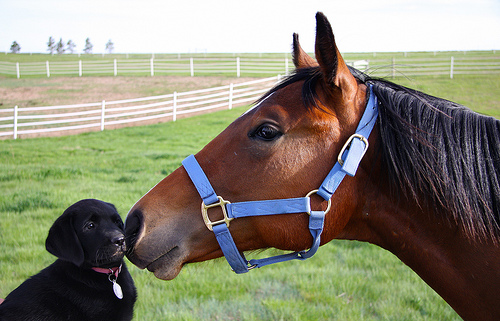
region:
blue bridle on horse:
[177, 155, 320, 307]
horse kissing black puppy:
[109, 206, 171, 272]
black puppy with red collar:
[48, 204, 133, 301]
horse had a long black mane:
[376, 90, 446, 172]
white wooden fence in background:
[71, 108, 129, 149]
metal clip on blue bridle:
[194, 190, 226, 253]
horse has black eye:
[245, 113, 270, 160]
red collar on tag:
[106, 278, 140, 315]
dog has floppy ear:
[46, 220, 73, 260]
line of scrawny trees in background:
[48, 34, 120, 77]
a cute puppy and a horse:
[45, 23, 445, 313]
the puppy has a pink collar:
[88, 259, 148, 277]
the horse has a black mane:
[351, 86, 498, 213]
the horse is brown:
[115, 8, 499, 290]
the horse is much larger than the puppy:
[6, 6, 485, 318]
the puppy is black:
[0, 190, 145, 318]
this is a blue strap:
[179, 75, 384, 272]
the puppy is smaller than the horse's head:
[0, 16, 392, 317]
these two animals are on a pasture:
[6, 10, 492, 317]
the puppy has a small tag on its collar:
[106, 270, 137, 310]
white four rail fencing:
[6, 86, 202, 141]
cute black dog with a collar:
[1, 183, 126, 318]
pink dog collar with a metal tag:
[88, 263, 131, 304]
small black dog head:
[43, 191, 125, 267]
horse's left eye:
[239, 116, 291, 159]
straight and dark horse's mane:
[376, 81, 498, 272]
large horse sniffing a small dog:
[0, 8, 497, 318]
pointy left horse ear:
[310, 10, 359, 85]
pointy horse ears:
[276, 8, 373, 93]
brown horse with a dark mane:
[124, 8, 498, 319]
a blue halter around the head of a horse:
[179, 78, 388, 277]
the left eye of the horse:
[247, 122, 287, 143]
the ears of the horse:
[290, 9, 347, 90]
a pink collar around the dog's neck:
[83, 264, 126, 277]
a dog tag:
[108, 275, 124, 300]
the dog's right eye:
[80, 219, 99, 231]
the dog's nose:
[107, 231, 129, 248]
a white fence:
[0, 53, 498, 141]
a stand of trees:
[7, 36, 118, 53]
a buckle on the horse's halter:
[336, 130, 371, 176]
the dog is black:
[30, 193, 147, 310]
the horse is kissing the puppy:
[7, 74, 429, 317]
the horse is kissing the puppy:
[31, 148, 209, 307]